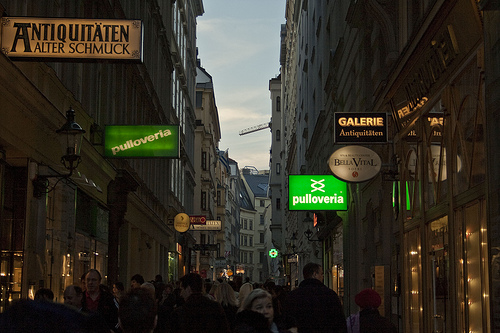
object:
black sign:
[334, 111, 386, 144]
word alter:
[34, 42, 66, 53]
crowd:
[2, 262, 391, 332]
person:
[239, 288, 279, 333]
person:
[80, 269, 115, 321]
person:
[157, 273, 230, 332]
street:
[2, 259, 340, 331]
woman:
[345, 288, 391, 332]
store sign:
[288, 174, 347, 210]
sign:
[1, 19, 140, 58]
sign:
[105, 125, 178, 159]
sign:
[326, 145, 382, 183]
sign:
[172, 212, 190, 232]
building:
[0, 0, 172, 332]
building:
[195, 68, 220, 281]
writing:
[10, 23, 130, 55]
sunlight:
[208, 3, 272, 168]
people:
[282, 262, 348, 333]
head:
[354, 288, 383, 313]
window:
[400, 227, 423, 330]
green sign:
[105, 125, 181, 158]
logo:
[311, 179, 325, 192]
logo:
[352, 171, 359, 178]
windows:
[249, 219, 253, 230]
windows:
[250, 253, 254, 264]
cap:
[355, 288, 382, 309]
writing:
[33, 42, 131, 55]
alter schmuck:
[34, 42, 132, 54]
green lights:
[269, 249, 279, 259]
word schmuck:
[69, 42, 134, 54]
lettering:
[339, 117, 383, 126]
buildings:
[268, 75, 285, 288]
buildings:
[239, 167, 268, 287]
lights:
[466, 232, 470, 236]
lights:
[410, 251, 417, 254]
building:
[347, 2, 497, 330]